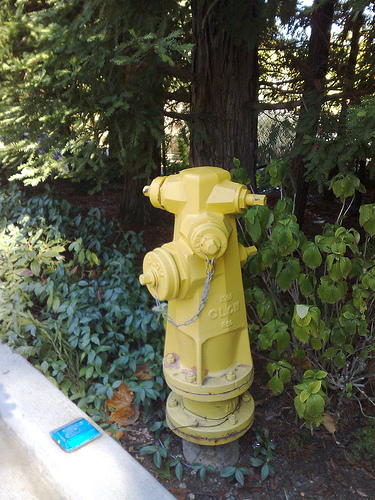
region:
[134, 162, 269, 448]
Yellow fire hydrant.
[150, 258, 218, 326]
Chain on the fire hydrant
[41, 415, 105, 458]
A blue reflector on the ground.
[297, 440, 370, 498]
Leaves on the dirt.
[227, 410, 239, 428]
A nut and bolt.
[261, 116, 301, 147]
A fence in the trees.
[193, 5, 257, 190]
The trunk of a tree.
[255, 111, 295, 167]
A chain link fence.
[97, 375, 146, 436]
A leaf in the bushes.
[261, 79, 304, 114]
Branches of the trees.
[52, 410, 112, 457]
light blue reflector on curb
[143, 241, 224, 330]
silver chain connected to fire hydrant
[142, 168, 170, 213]
circular valve on left side of hydrant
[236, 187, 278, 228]
upper right valve on right side of hydrant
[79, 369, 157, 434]
brown dead leaves on ground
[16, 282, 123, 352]
green leave on ground on left side of picture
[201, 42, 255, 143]
brown wooden tree trunk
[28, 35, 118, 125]
green tree leaves from left side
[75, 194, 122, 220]
brown dirt under tree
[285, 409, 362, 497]
brown dirt to right of hydrant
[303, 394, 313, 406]
the leaves are green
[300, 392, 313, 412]
the leaves are green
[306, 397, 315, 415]
the leaves are green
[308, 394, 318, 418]
the leaves are green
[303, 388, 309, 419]
the leaves are green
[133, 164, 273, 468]
The yellow fire hydrant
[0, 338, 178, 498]
The concrete curb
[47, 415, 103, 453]
The blue reflector on the curb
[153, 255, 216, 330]
The chair on the fire hydrant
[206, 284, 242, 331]
The writing on the side of the hydrant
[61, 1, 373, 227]
The tree trunks behind the fire hydrant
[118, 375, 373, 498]
The dirt next to the fire hydrant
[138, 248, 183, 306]
The larger cover connected to the chain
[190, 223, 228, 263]
The smaller cover connected to the chain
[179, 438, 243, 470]
THe grey base of the fire hydrant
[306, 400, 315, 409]
the leaves are green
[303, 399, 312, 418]
the leaves are green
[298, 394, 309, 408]
the leaves are green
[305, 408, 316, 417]
the leaves are green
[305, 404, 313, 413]
the leaves are green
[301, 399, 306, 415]
the leaves are green